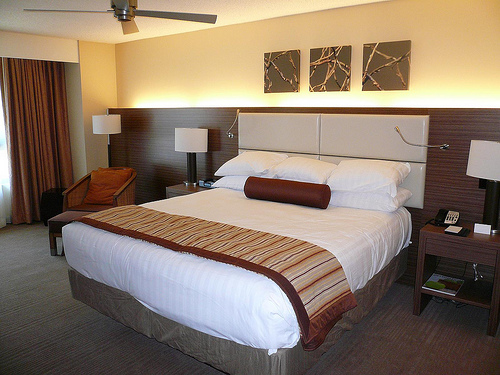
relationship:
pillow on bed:
[241, 172, 338, 211] [52, 143, 413, 373]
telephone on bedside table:
[433, 205, 461, 226] [410, 215, 500, 337]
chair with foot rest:
[43, 166, 136, 256] [46, 210, 98, 255]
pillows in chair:
[83, 163, 135, 206] [45, 162, 140, 258]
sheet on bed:
[66, 187, 412, 344] [52, 143, 413, 373]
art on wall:
[260, 31, 426, 98] [435, 38, 475, 87]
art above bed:
[260, 49, 304, 95] [56, 110, 436, 374]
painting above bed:
[305, 43, 358, 94] [56, 110, 436, 374]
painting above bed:
[350, 32, 418, 95] [56, 110, 436, 374]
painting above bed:
[360, 37, 415, 92] [56, 110, 436, 374]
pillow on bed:
[221, 146, 284, 194] [52, 143, 413, 373]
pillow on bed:
[277, 145, 337, 185] [52, 143, 413, 373]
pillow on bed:
[324, 149, 418, 219] [52, 143, 413, 373]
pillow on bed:
[211, 148, 286, 178] [63, 127, 401, 341]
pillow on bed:
[327, 158, 412, 194] [56, 110, 436, 374]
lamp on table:
[172, 126, 209, 188] [167, 182, 201, 194]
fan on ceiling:
[20, 1, 224, 38] [0, 0, 370, 52]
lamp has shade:
[459, 131, 499, 233] [457, 128, 497, 189]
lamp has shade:
[172, 122, 222, 189] [174, 117, 212, 158]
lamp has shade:
[90, 113, 121, 165] [91, 113, 122, 133]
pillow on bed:
[241, 172, 338, 211] [118, 117, 385, 353]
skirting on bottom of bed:
[61, 264, 275, 369] [52, 143, 413, 373]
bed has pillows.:
[56, 110, 436, 374] [209, 146, 414, 213]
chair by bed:
[48, 168, 131, 265] [56, 110, 436, 374]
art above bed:
[260, 49, 304, 95] [84, 92, 421, 372]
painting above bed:
[305, 43, 358, 94] [84, 92, 421, 372]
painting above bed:
[360, 37, 415, 92] [84, 92, 421, 372]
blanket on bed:
[78, 190, 352, 342] [56, 110, 436, 374]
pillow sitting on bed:
[323, 158, 413, 197] [66, 158, 413, 353]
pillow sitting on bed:
[324, 183, 415, 214] [66, 158, 413, 353]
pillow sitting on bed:
[274, 154, 339, 184] [66, 158, 413, 353]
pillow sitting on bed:
[246, 177, 326, 207] [66, 158, 413, 353]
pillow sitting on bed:
[211, 148, 286, 178] [66, 158, 413, 353]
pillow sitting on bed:
[215, 176, 242, 187] [66, 158, 413, 353]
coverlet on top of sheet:
[141, 208, 316, 282] [224, 190, 331, 253]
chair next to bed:
[43, 166, 136, 256] [52, 143, 413, 373]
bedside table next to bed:
[410, 215, 500, 337] [56, 110, 436, 374]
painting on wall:
[360, 37, 415, 92] [115, 0, 498, 270]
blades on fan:
[28, 0, 221, 41] [20, 1, 224, 37]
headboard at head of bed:
[236, 112, 430, 212] [61, 202, 408, 373]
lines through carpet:
[340, 338, 362, 359] [398, 322, 460, 363]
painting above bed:
[272, 27, 386, 95] [74, 156, 329, 324]